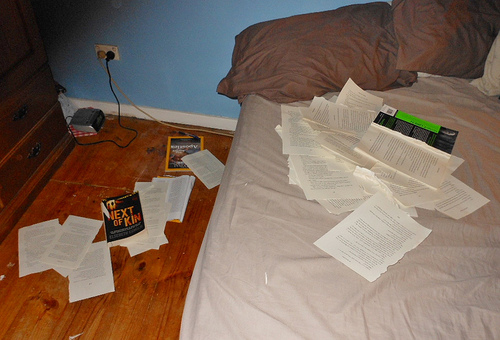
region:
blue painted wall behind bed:
[32, 0, 387, 117]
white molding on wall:
[62, 92, 234, 129]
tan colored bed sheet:
[180, 76, 495, 332]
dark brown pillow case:
[215, 1, 415, 101]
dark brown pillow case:
[390, 0, 495, 80]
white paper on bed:
[310, 191, 430, 278]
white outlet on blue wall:
[91, 41, 116, 58]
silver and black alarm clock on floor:
[66, 105, 102, 130]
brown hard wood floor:
[0, 115, 230, 335]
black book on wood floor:
[101, 190, 146, 241]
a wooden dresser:
[2, 5, 88, 261]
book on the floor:
[100, 121, 216, 251]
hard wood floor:
[116, 261, 176, 338]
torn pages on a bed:
[271, 77, 479, 279]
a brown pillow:
[219, 10, 416, 95]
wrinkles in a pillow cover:
[317, 17, 398, 78]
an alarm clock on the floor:
[66, 91, 116, 144]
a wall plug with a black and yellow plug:
[93, 38, 119, 64]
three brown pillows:
[215, 6, 497, 99]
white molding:
[90, 94, 229, 136]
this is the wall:
[149, 19, 198, 83]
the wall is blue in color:
[149, 30, 186, 60]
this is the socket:
[96, 44, 121, 61]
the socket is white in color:
[99, 42, 111, 52]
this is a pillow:
[269, 27, 326, 62]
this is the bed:
[246, 88, 483, 335]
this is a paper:
[364, 217, 380, 245]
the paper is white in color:
[348, 212, 378, 257]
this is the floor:
[63, 151, 97, 201]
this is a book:
[105, 197, 140, 236]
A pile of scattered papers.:
[273, 76, 490, 283]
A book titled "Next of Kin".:
[99, 189, 149, 249]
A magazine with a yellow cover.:
[163, 135, 204, 172]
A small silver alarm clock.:
[69, 107, 106, 133]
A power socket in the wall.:
[93, 42, 120, 62]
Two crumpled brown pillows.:
[214, 0, 499, 105]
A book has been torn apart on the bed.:
[273, 76, 491, 286]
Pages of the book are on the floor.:
[17, 148, 224, 303]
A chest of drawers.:
[1, 0, 78, 243]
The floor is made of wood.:
[1, 111, 233, 338]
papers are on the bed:
[251, 72, 489, 334]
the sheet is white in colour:
[244, 273, 494, 306]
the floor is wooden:
[21, 290, 189, 338]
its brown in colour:
[20, 283, 193, 339]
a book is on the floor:
[64, 193, 184, 259]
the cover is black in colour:
[87, 176, 164, 252]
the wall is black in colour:
[129, 17, 196, 101]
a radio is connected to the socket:
[51, 93, 161, 155]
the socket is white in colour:
[92, 30, 134, 75]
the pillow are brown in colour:
[214, 23, 371, 105]